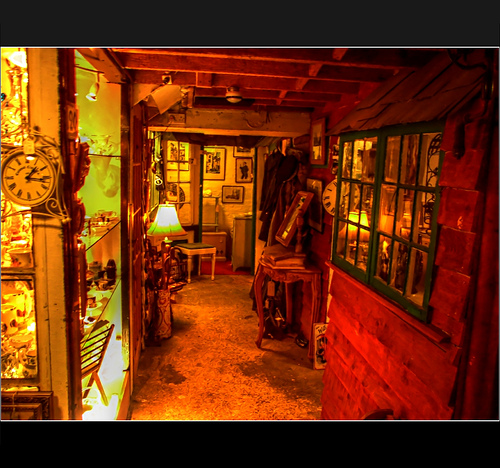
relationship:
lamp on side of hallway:
[145, 203, 187, 250] [175, 269, 259, 420]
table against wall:
[249, 234, 349, 366] [283, 135, 334, 255]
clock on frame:
[6, 138, 83, 220] [31, 49, 66, 421]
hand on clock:
[27, 177, 44, 180] [0, 147, 59, 207]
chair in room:
[173, 235, 217, 281] [2, 45, 491, 420]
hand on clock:
[24, 176, 45, 183] [1, 149, 54, 206]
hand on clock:
[25, 166, 39, 180] [1, 149, 54, 206]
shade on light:
[140, 204, 187, 236] [153, 206, 180, 226]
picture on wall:
[204, 146, 227, 181] [149, 132, 253, 234]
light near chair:
[143, 202, 186, 289] [176, 242, 216, 283]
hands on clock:
[22, 167, 46, 184] [0, 117, 72, 220]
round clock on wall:
[318, 172, 362, 222] [310, 133, 331, 258]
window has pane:
[330, 118, 448, 324] [341, 144, 356, 178]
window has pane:
[330, 114, 445, 324] [350, 223, 385, 281]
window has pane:
[330, 114, 445, 324] [405, 245, 428, 307]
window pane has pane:
[351, 225, 373, 275] [343, 174, 363, 224]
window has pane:
[330, 118, 448, 324] [343, 222, 359, 267]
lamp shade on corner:
[147, 203, 185, 240] [142, 125, 188, 293]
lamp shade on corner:
[147, 203, 185, 240] [148, 145, 188, 301]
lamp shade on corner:
[147, 203, 185, 240] [126, 117, 183, 348]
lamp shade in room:
[147, 203, 185, 240] [2, 45, 491, 420]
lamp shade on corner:
[147, 203, 185, 240] [145, 129, 175, 288]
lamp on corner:
[146, 204, 189, 240] [146, 135, 187, 292]